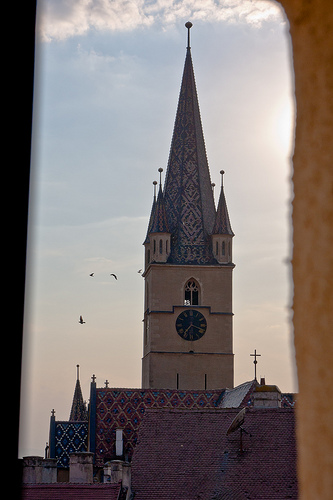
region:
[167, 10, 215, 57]
top part of building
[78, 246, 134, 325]
birds in the sky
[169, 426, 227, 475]
roof of a building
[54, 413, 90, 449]
pattern on a building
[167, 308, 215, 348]
clock on the tower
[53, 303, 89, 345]
bird in the air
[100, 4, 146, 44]
white clouds in the sky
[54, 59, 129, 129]
blue sky in the daytime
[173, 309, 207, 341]
black and gold clock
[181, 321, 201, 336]
two hands of clock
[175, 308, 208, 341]
Large clock on the side of a tower.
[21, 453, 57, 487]
Two chimneys on the left.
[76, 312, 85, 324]
A black bird flying.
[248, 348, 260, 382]
A large thin cross on a roof to the right.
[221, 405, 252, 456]
A satellite dish on a roof.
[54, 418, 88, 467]
A decorative blue colored diamond roof.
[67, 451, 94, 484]
The tallest chimney on the bottom left.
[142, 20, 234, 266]
A tall steeple on a tower.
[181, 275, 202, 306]
An arched window over a clock.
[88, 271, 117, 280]
Two birds flying close together.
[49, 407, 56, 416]
a small stone cross on a beautiful church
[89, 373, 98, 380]
a small stone cross on a beautiful church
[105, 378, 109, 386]
a small stone cross on a beautiful church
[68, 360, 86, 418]
a narrow tower of a roof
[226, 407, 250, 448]
a grey dish on a roof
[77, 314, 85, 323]
a bird flying in the air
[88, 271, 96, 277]
a bird flying in the air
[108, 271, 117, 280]
a bird flying in the air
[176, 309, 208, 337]
a gold and black clock face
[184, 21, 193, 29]
a round ball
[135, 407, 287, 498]
A roof with a sattelite dish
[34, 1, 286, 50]
Patchy clouds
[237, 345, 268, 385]
Cross on top of a building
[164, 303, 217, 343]
A black clock Roman numerals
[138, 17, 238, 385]
A clock tower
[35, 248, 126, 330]
Three birds flying in a partly cloudy sky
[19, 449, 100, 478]
Stone smokestacks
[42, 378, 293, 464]
Mosaic covered rooftops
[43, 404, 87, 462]
Roof with blue diamond pattern and a cross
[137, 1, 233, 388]
Tower with four spires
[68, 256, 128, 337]
three birds flying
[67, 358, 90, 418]
top of a building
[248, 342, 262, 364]
cross on top of church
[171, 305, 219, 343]
clock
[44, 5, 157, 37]
clouds over blue sky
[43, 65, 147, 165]
view of blue sky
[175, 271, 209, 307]
window on church clock tower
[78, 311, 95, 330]
bird flying away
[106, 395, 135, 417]
pattern on the rooftop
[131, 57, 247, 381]
tall church tower with decorated top